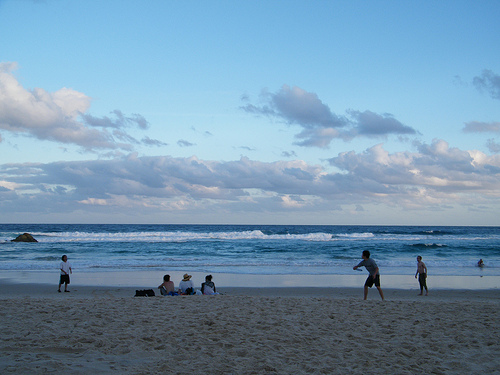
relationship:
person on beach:
[156, 273, 178, 296] [4, 274, 491, 372]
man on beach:
[350, 250, 383, 302] [44, 195, 498, 372]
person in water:
[466, 257, 491, 271] [4, 219, 498, 289]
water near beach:
[4, 219, 498, 289] [4, 274, 491, 372]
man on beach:
[350, 250, 383, 302] [5, 256, 495, 373]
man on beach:
[410, 254, 430, 298] [36, 219, 499, 370]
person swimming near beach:
[474, 258, 483, 270] [4, 274, 491, 372]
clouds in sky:
[2, 54, 496, 219] [2, 1, 498, 226]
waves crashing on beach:
[1, 215, 499, 265] [4, 232, 498, 373]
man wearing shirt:
[53, 250, 76, 291] [59, 261, 72, 274]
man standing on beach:
[410, 250, 435, 299] [0, 276, 499, 374]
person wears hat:
[178, 273, 196, 296] [182, 273, 189, 277]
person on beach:
[199, 270, 218, 295] [4, 232, 498, 373]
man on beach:
[55, 253, 76, 295] [4, 274, 491, 372]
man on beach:
[410, 254, 430, 298] [5, 256, 495, 373]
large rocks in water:
[18, 220, 60, 267] [1, 223, 498, 285]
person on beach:
[178, 272, 194, 292] [43, 239, 430, 371]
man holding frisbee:
[353, 248, 386, 301] [355, 267, 363, 272]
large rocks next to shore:
[10, 232, 42, 244] [0, 238, 500, 372]